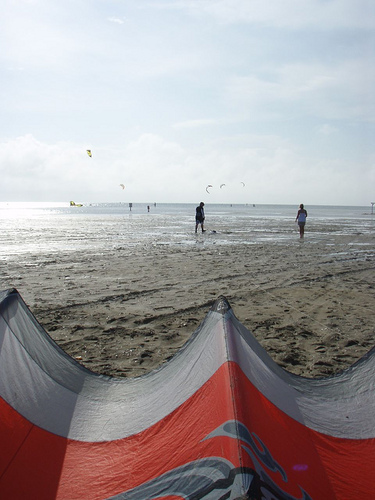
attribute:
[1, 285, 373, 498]
tarp — red, white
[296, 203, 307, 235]
person — white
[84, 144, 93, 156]
kite — yellow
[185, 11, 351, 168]
sky — blue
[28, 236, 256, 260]
sand — wet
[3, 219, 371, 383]
sand — wet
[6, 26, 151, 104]
clouds — white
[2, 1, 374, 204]
sky — blue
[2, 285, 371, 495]
hang glider — red, gray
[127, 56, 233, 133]
clouds — white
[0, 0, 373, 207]
clouds — white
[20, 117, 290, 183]
clouds — white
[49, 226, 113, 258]
sand — wet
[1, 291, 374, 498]
sail — red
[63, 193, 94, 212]
equipment — yellow